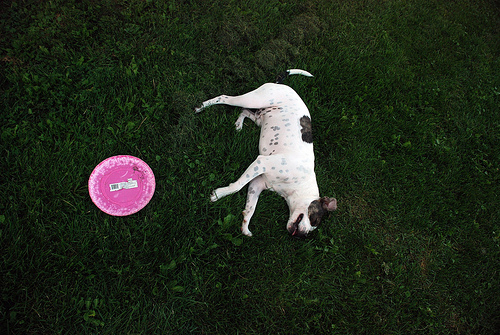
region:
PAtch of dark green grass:
[22, 277, 71, 322]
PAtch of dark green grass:
[75, 273, 141, 333]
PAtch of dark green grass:
[149, 265, 201, 328]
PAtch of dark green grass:
[209, 261, 248, 332]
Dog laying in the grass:
[190, 47, 424, 312]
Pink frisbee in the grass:
[69, 144, 179, 239]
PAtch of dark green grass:
[424, 236, 456, 316]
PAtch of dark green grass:
[382, 178, 437, 235]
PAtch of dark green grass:
[310, 269, 359, 319]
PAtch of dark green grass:
[128, 67, 223, 133]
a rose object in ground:
[95, 133, 182, 238]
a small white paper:
[103, 170, 150, 200]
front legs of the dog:
[200, 172, 278, 246]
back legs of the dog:
[183, 83, 268, 132]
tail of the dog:
[283, 63, 339, 93]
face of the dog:
[283, 192, 370, 259]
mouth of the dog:
[283, 220, 309, 238]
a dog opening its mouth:
[288, 200, 368, 262]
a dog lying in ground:
[199, 33, 381, 242]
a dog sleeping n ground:
[171, 62, 351, 247]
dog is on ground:
[188, 60, 340, 250]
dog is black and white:
[200, 63, 345, 248]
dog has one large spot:
[298, 113, 312, 143]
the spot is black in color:
[299, 114, 314, 144]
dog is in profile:
[195, 57, 339, 239]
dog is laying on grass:
[198, 63, 340, 236]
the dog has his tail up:
[278, 65, 310, 80]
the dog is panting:
[286, 209, 308, 234]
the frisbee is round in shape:
[91, 154, 158, 218]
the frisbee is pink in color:
[87, 154, 155, 215]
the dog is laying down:
[197, 57, 385, 290]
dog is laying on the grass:
[173, 0, 355, 274]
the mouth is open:
[267, 207, 311, 259]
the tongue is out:
[273, 217, 305, 241]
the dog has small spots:
[213, 79, 303, 181]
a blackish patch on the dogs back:
[295, 102, 323, 162]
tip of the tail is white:
[270, 45, 337, 84]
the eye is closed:
[305, 205, 327, 240]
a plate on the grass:
[61, 138, 180, 261]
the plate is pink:
[62, 125, 187, 242]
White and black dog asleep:
[172, 55, 340, 256]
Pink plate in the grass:
[68, 143, 183, 240]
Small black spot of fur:
[295, 111, 326, 150]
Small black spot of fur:
[260, 144, 273, 157]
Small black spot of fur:
[263, 119, 287, 153]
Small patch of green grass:
[389, 248, 451, 311]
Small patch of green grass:
[390, 169, 435, 220]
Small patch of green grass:
[428, 274, 473, 327]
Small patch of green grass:
[403, 204, 455, 245]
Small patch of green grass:
[351, 132, 438, 186]